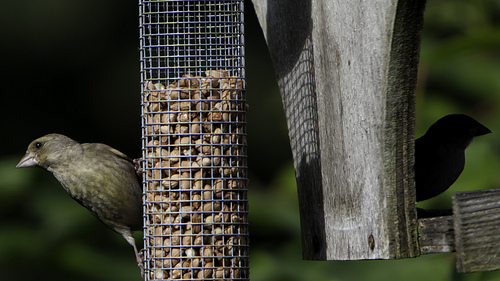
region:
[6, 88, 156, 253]
the bird is hanging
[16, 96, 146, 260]
its grey in colour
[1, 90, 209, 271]
it is on a post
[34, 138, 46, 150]
its eyes are blac in colour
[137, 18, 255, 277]
the tube is made from a chain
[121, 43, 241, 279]
it has beans inside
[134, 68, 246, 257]
the beans are brown in colour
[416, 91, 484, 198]
the bird is black in colour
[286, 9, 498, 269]
it is on a wooden plank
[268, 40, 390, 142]
the plank is grey in colour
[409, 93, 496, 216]
bird in the shadows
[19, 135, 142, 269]
bird clinging to wire feeder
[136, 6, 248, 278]
wire bird feeder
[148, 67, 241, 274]
feed inside wire bird feather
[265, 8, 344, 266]
shadow on wood bracket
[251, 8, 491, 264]
wood bracket feeder is attached to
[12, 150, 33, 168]
beak of bird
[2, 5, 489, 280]
green foliage in the background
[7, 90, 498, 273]
two birds on bird feeder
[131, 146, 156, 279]
talons of the bird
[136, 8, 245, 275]
cylinder shaped bird feeder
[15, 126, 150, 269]
bird perching on wire bird feeder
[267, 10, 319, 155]
shadow of wire on wood post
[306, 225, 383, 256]
screws in the wood bracket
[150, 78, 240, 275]
food inside the bird feeder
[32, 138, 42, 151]
black eye of the bird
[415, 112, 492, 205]
bird perched in the shadows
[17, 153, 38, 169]
white beak of the bird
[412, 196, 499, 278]
wood board bird is perched on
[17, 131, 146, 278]
brown bird on bird feeder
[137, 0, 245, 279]
bird feeder filled with nuts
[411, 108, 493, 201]
small shadow of a bird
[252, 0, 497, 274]
wooden holder for bird feeder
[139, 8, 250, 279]
wire boxes allowing food to get through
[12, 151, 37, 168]
small pointy beak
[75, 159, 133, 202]
hint of yellow on belly feathers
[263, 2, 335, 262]
shadow cast by feeder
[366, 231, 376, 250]
rust nail in wood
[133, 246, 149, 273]
small pink talons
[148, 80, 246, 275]
bird feed in container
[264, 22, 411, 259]
bottom of the tree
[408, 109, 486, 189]
black bird looking left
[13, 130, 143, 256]
bird sitting on feeder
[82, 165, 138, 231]
bird has yellow on his stomach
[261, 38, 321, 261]
reflection on the tree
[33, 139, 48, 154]
eye of bird is black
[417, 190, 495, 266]
pieces of wood on the ground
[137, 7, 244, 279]
feeder is not filled to top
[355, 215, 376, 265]
knot in the wood